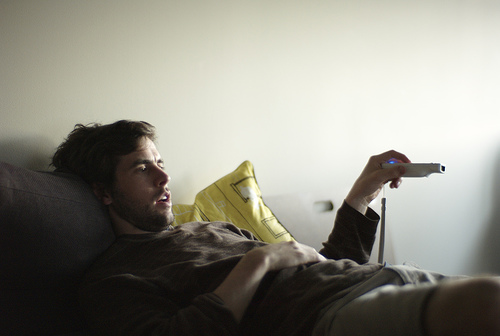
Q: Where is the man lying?
A: Bed.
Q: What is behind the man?
A: Yellow pillow.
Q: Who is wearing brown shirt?
A: Man lying down.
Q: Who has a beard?
A: The man on the bed.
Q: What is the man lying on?
A: The bed.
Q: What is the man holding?
A: Remote.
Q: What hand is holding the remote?
A: Left.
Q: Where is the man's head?
A: On the pillow.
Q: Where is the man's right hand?
A: On his stomach.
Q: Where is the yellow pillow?
A: On the bed.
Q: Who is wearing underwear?
A: The man.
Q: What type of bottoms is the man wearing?
A: Underwear.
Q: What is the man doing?
A: Laying down.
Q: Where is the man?
A: Lying down.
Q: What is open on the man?
A: Mouth.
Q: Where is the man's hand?
A: On the stomach.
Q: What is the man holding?
A: Controller.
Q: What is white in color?
A: Wall.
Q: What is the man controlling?
A: A game.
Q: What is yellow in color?
A: Pillow.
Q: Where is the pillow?
A: Near the man.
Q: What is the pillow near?
A: Wall.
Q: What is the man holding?
A: A remote.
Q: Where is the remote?
A: Man's hand.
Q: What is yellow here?
A: Pillow.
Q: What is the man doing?
A: Watching tv.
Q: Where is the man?
A: In bed.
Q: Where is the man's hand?
A: On her stomach.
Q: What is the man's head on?
A: A pillow.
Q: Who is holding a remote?
A: The man.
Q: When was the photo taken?
A: Night.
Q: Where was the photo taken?
A: Bedroom.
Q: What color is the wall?
A: Ivory.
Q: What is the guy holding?
A: Remote.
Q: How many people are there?
A: One.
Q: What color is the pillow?
A: Yellow.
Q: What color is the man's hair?
A: Brown.